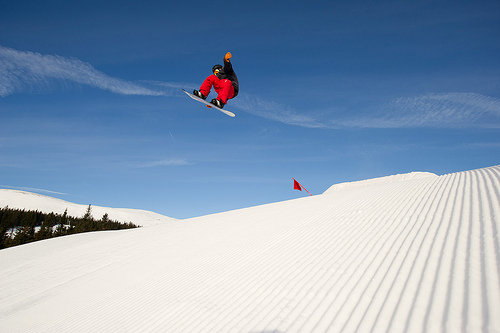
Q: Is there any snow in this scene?
A: Yes, there is snow.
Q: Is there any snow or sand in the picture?
A: Yes, there is snow.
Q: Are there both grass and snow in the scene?
A: No, there is snow but no grass.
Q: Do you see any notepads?
A: No, there are no notepads.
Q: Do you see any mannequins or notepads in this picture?
A: No, there are no notepads or mannequins.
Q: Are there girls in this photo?
A: No, there are no girls.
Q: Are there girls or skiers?
A: No, there are no girls or skiers.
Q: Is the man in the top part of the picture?
A: Yes, the man is in the top of the image.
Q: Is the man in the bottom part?
A: No, the man is in the top of the image.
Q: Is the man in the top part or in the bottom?
A: The man is in the top of the image.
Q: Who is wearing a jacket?
A: The man is wearing a jacket.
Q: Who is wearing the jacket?
A: The man is wearing a jacket.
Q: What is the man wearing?
A: The man is wearing a jacket.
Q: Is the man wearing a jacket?
A: Yes, the man is wearing a jacket.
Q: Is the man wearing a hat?
A: No, the man is wearing a jacket.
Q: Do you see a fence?
A: No, there are no fences.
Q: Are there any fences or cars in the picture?
A: No, there are no fences or cars.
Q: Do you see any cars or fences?
A: No, there are no fences or cars.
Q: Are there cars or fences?
A: No, there are no fences or cars.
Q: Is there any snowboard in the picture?
A: Yes, there is a snowboard.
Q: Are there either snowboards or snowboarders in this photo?
A: Yes, there is a snowboard.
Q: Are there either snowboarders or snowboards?
A: Yes, there is a snowboard.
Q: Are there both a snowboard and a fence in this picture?
A: No, there is a snowboard but no fences.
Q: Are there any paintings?
A: No, there are no paintings.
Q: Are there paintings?
A: No, there are no paintings.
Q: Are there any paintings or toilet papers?
A: No, there are no paintings or toilet papers.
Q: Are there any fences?
A: No, there are no fences.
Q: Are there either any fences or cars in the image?
A: No, there are no fences or cars.